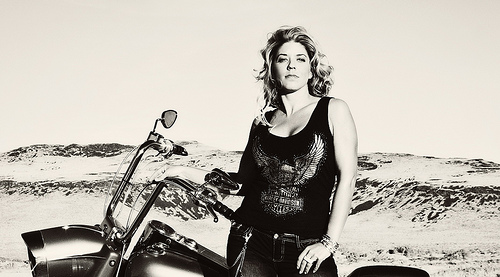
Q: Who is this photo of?
A: A biker chick.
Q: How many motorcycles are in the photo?
A: One.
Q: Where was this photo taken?
A: The mountains.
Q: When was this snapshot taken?
A: 1963.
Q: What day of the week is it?
A: Friday.